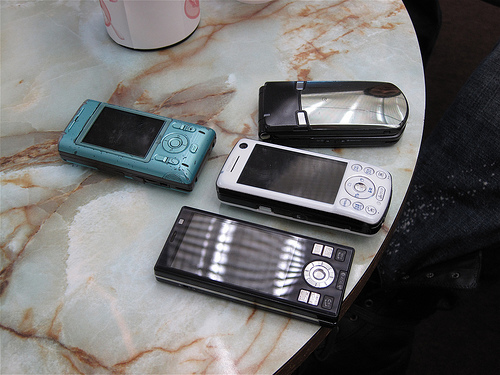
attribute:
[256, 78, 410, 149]
cell phone — old, black, flip phone, closed, silver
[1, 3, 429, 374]
table — white, marble, round, brown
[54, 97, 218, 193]
camera — blue, small, off, green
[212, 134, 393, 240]
cell phone — white, smartphone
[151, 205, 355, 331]
cell phone — black, new, smartphone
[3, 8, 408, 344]
design — brown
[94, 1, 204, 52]
cup — white, paper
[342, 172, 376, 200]
control — round